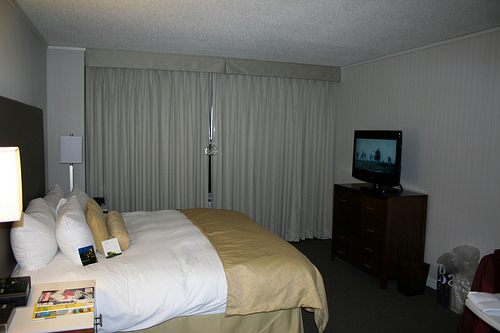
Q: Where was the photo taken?
A: Motel room.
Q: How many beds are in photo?
A: One.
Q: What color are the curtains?
A: White.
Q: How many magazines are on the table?
A: Three.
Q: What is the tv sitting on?
A: Chest of drawers.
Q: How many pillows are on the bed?
A: Six.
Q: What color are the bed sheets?
A: White.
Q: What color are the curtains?
A: White.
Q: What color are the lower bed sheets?
A: Gold.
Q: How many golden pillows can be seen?
A: Two.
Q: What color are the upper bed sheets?
A: White.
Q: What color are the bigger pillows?
A: White.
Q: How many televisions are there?
A: One.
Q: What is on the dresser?
A: A television.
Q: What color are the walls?
A: White.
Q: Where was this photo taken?
A: In a hotel room.